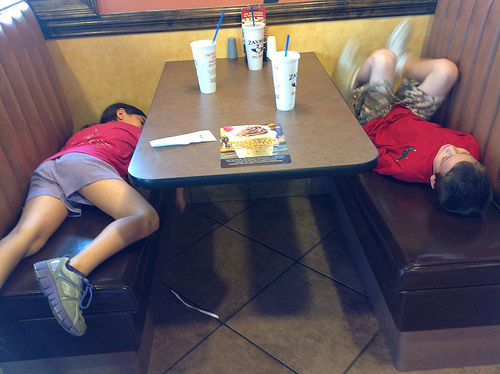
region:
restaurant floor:
[0, 177, 497, 372]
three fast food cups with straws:
[188, 5, 299, 114]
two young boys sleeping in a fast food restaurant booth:
[1, 0, 495, 371]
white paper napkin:
[150, 129, 215, 146]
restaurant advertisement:
[219, 121, 289, 167]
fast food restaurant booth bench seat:
[341, 0, 498, 370]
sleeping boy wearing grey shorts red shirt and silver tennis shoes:
[0, 104, 160, 339]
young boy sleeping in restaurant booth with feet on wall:
[338, 20, 491, 217]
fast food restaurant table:
[128, 50, 378, 188]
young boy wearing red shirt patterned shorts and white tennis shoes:
[334, 17, 492, 215]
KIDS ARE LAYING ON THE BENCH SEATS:
[33, 108, 491, 331]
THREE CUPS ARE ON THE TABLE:
[185, 6, 310, 121]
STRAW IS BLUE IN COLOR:
[206, 10, 226, 45]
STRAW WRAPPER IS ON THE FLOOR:
[167, 282, 227, 343]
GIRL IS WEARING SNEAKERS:
[35, 247, 90, 329]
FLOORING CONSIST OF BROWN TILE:
[173, 211, 369, 362]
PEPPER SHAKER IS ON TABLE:
[223, 31, 249, 62]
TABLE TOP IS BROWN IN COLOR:
[130, 50, 371, 176]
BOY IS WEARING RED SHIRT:
[358, 105, 469, 163]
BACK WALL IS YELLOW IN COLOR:
[64, 40, 425, 82]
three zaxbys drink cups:
[188, 21, 298, 114]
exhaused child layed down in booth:
[3, 102, 159, 335]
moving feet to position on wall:
[332, 18, 492, 217]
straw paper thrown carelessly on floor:
[167, 284, 219, 320]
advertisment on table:
[219, 125, 291, 165]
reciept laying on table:
[145, 126, 217, 145]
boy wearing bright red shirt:
[356, 106, 478, 178]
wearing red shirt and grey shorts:
[28, 121, 140, 218]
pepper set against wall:
[223, 39, 237, 59]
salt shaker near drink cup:
[261, 34, 276, 62]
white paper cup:
[257, 27, 305, 110]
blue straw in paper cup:
[281, 30, 293, 65]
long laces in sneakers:
[56, 273, 108, 316]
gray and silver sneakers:
[27, 257, 110, 347]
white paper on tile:
[167, 280, 240, 325]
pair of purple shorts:
[32, 144, 130, 209]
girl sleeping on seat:
[41, 98, 153, 277]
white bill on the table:
[147, 125, 222, 162]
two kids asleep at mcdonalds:
[28, 16, 498, 335]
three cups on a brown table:
[178, 24, 310, 109]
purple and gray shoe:
[30, 258, 112, 331]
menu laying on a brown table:
[217, 118, 292, 182]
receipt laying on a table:
[148, 123, 220, 152]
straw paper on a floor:
[163, 268, 265, 346]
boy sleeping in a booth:
[327, 40, 496, 222]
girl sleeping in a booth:
[8, 70, 170, 314]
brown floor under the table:
[177, 241, 346, 364]